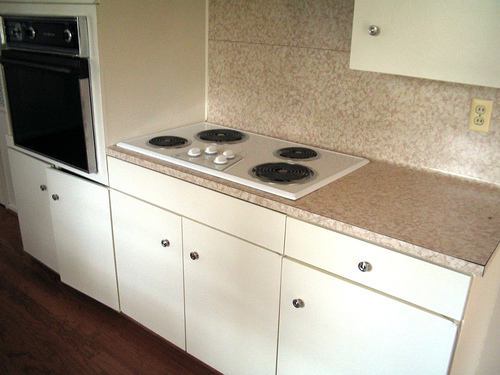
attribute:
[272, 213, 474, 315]
drawer — white, cabinet drawer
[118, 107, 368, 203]
cook top — electric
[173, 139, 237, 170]
knobs — white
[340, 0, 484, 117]
cabinet — white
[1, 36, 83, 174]
black oven — above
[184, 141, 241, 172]
dials on oven — three, black, chrome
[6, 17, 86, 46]
chrome oven doors — black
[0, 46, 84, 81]
oven handle — black, chrome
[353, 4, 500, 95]
single white cabinet — above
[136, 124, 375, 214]
stove — white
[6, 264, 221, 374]
floor is dark — dark wood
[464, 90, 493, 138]
outlet under cabinet — electric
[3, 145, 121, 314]
door is not closed — cabinet door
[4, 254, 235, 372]
hardwood floors — old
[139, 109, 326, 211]
counter stove — white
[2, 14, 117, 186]
dish washer — silver, black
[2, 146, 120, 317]
cabinet open — white